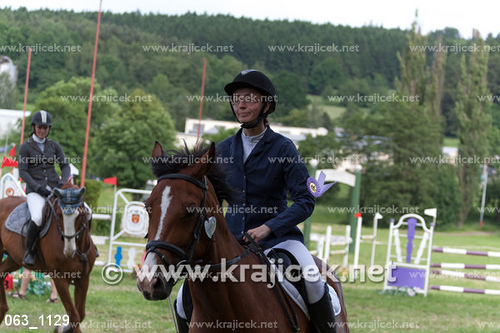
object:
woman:
[14, 109, 100, 268]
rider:
[170, 70, 335, 333]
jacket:
[194, 123, 322, 254]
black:
[31, 116, 40, 124]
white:
[40, 111, 47, 116]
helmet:
[222, 69, 277, 113]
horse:
[134, 135, 350, 331]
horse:
[0, 177, 101, 332]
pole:
[430, 248, 500, 258]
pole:
[430, 261, 499, 271]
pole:
[428, 269, 499, 283]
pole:
[428, 284, 500, 295]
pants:
[25, 191, 92, 228]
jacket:
[17, 134, 71, 194]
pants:
[174, 240, 325, 320]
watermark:
[264, 42, 362, 53]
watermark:
[323, 91, 420, 106]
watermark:
[97, 257, 397, 288]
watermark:
[405, 154, 499, 166]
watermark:
[5, 154, 82, 164]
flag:
[101, 177, 116, 188]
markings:
[143, 185, 173, 282]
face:
[138, 176, 206, 300]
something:
[143, 168, 215, 258]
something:
[52, 186, 84, 244]